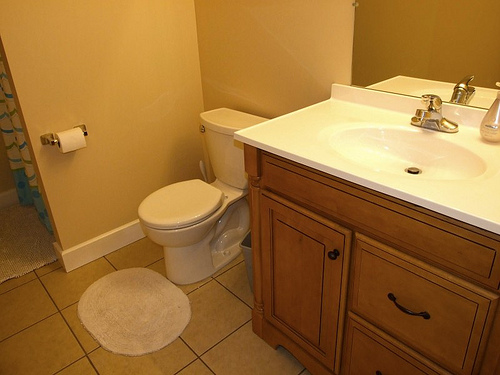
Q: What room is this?
A: Bathroom.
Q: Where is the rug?
A: In front of the toilet.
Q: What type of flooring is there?
A: Tile.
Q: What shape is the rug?
A: Oval.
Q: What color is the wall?
A: Yellow.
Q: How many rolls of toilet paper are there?
A: One.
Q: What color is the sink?
A: White.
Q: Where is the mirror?
A: Over the sink.